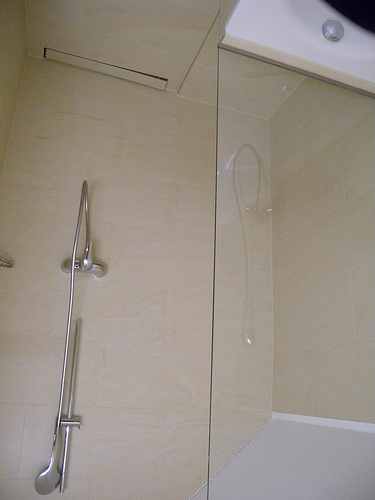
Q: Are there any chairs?
A: No, there are no chairs.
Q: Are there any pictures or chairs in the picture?
A: No, there are no chairs or pictures.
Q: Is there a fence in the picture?
A: No, there are no fences.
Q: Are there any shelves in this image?
A: No, there are no shelves.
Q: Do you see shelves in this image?
A: No, there are no shelves.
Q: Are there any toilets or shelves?
A: No, there are no shelves or toilets.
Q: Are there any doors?
A: Yes, there is a door.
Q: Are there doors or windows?
A: Yes, there is a door.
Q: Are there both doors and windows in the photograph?
A: No, there is a door but no windows.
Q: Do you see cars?
A: No, there are no cars.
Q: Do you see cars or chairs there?
A: No, there are no cars or chairs.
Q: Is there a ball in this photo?
A: No, there are no balls.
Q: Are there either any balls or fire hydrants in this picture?
A: No, there are no balls or fire hydrants.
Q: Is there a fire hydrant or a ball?
A: No, there are no balls or fire hydrants.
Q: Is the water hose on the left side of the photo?
A: Yes, the water hose is on the left of the image.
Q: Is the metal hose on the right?
A: No, the hose is on the left of the image.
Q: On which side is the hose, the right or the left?
A: The hose is on the left of the image.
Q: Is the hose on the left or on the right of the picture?
A: The hose is on the left of the image.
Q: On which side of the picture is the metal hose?
A: The hose is on the left of the image.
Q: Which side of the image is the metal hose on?
A: The hose is on the left of the image.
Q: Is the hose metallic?
A: Yes, the hose is metallic.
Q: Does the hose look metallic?
A: Yes, the hose is metallic.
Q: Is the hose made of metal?
A: Yes, the hose is made of metal.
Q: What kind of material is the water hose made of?
A: The water hose is made of metal.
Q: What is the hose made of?
A: The water hose is made of metal.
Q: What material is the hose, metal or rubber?
A: The hose is made of metal.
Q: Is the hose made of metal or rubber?
A: The hose is made of metal.